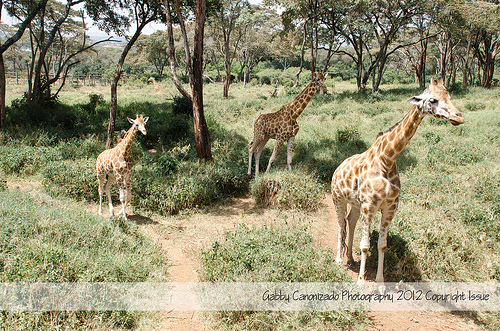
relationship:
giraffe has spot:
[328, 76, 464, 288] [370, 175, 385, 193]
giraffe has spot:
[328, 76, 464, 288] [383, 142, 395, 156]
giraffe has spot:
[328, 76, 464, 288] [402, 122, 414, 136]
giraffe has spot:
[328, 76, 464, 288] [343, 174, 351, 192]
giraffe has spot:
[328, 76, 464, 288] [359, 204, 368, 214]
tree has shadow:
[12, 75, 90, 146] [10, 102, 113, 144]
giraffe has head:
[94, 113, 150, 221] [125, 112, 148, 132]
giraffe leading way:
[246, 72, 329, 180] [365, 278, 452, 329]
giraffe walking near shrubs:
[328, 76, 464, 288] [194, 214, 383, 329]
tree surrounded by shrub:
[159, 0, 231, 167] [130, 143, 222, 208]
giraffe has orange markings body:
[328, 76, 464, 288] [330, 135, 406, 280]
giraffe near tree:
[351, 100, 438, 262] [172, 20, 217, 151]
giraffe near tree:
[246, 72, 329, 180] [101, 55, 125, 130]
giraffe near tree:
[94, 113, 150, 221] [303, 29, 319, 71]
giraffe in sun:
[328, 76, 464, 288] [13, 46, 95, 104]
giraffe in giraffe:
[244, 69, 335, 176] [92, 113, 149, 221]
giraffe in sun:
[92, 113, 149, 221] [13, 46, 95, 104]